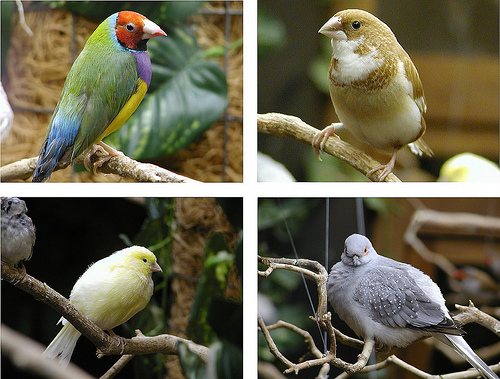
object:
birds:
[32, 8, 466, 365]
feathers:
[323, 233, 465, 352]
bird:
[28, 11, 173, 185]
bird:
[40, 244, 167, 369]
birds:
[27, 9, 433, 183]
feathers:
[131, 50, 151, 88]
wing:
[68, 51, 134, 161]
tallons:
[306, 125, 400, 182]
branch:
[2, 146, 217, 181]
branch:
[2, 265, 182, 379]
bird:
[325, 233, 467, 352]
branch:
[305, 346, 493, 377]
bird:
[309, 9, 433, 180]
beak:
[318, 16, 349, 41]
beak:
[146, 25, 168, 38]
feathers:
[30, 117, 80, 183]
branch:
[257, 112, 400, 182]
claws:
[108, 334, 128, 354]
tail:
[41, 311, 85, 366]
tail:
[28, 139, 75, 183]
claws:
[82, 143, 121, 175]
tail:
[437, 324, 495, 378]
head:
[339, 232, 374, 267]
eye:
[143, 258, 148, 263]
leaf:
[129, 33, 227, 165]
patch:
[325, 35, 376, 81]